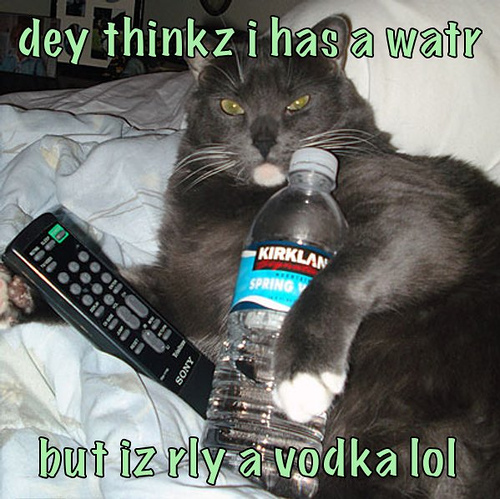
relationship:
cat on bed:
[199, 54, 422, 281] [63, 86, 138, 200]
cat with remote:
[199, 54, 422, 281] [30, 213, 189, 381]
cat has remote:
[199, 54, 422, 281] [30, 213, 189, 381]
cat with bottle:
[199, 54, 422, 281] [260, 197, 328, 319]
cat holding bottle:
[199, 54, 422, 281] [260, 197, 328, 319]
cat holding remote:
[199, 54, 422, 281] [30, 213, 189, 381]